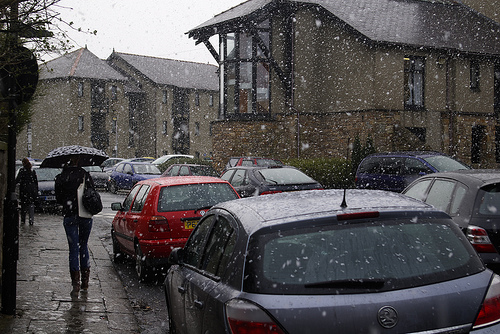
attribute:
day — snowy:
[0, 2, 491, 328]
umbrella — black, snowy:
[40, 144, 108, 169]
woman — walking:
[53, 165, 103, 295]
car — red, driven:
[115, 180, 229, 258]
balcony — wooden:
[211, 30, 280, 126]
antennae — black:
[334, 144, 355, 208]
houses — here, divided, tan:
[29, 0, 497, 176]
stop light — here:
[2, 4, 47, 332]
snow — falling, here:
[3, 1, 497, 317]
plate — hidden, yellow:
[183, 219, 201, 229]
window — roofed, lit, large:
[216, 18, 271, 116]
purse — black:
[78, 175, 101, 215]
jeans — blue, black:
[62, 210, 101, 284]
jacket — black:
[53, 173, 90, 221]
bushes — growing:
[193, 148, 375, 193]